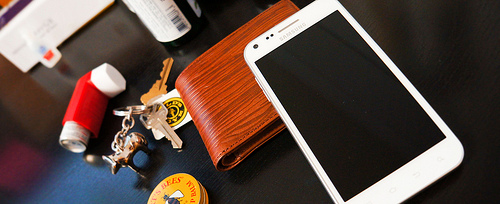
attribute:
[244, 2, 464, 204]
cellphone — white, smartphone, off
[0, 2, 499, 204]
table — wooden, wood, dark brown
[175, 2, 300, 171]
wallet — brown, man's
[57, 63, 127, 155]
inhaler — red, white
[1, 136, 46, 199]
reflection — red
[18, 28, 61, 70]
bottle — small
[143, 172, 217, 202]
container — yellow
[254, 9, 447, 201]
screen — black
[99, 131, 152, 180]
animal — statue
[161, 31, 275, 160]
wallet — woodgrain look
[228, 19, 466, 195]
phone — samsung, white, smart